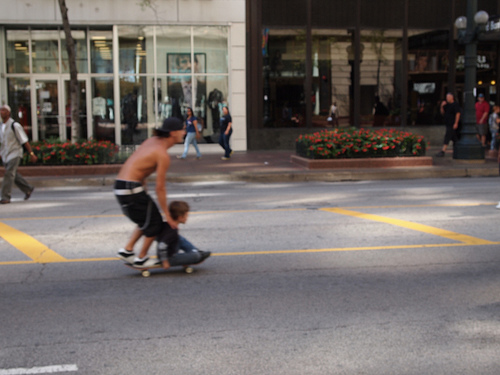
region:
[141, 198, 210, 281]
a child sitting on a skateboard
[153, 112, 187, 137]
a black baseball cap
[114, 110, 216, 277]
a man riding on a skateboard with a child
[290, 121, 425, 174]
a bed of red flowers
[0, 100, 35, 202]
a man walking in the crosswalk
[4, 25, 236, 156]
storefront windows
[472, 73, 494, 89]
yellow lights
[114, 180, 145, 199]
white belt around jean shorts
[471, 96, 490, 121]
a red tee shirt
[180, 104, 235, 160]
two girls on the sidewalk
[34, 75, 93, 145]
the door to the building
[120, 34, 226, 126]
windows on the building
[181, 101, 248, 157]
people walking in front of the building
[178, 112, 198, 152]
a girl in a blue shirt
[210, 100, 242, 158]
a person in a black shirt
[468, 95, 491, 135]
a person in a red shirt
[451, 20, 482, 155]
a lamp post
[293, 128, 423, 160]
red flowers on the sidewalk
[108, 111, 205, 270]
two people on a skateboard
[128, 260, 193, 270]
a skateboard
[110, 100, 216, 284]
the man and boy skateboard on the street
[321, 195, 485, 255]
the orange traffic markings on the gorund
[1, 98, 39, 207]
the man wlaking across the street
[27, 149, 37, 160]
the watch on the wrist of the man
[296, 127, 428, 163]
the red plants on the sidewalk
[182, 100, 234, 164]
the people walking on the sidewalk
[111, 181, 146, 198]
the white belt on the skater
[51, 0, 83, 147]
the tree trunk in front of the building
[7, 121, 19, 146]
the black strap on the shoulder of the man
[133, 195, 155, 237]
the chain on the pants of the man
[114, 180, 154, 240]
the shorts are black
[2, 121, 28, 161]
the shirt is white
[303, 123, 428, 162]
a group of flowers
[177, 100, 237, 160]
two people walking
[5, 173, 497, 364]
the road is grey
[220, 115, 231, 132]
the shirt is black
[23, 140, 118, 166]
a bed or red flowers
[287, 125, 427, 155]
a bed or red flowers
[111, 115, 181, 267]
a guy without a shirt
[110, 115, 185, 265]
a guy wearing a black hat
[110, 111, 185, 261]
a guy wearing shorts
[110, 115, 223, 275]
a guy and a boy on a skateboard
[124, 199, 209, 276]
youg boy sitting on a skateboard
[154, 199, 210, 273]
a boy wearing a black shirt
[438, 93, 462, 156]
a man wearing a black shirt